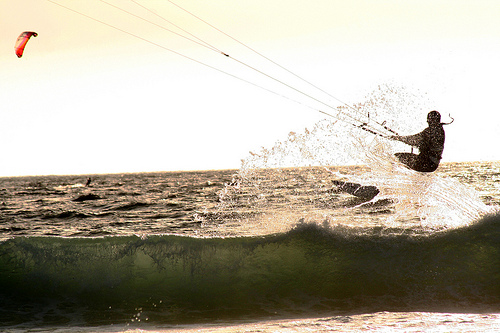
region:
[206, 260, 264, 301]
part of a water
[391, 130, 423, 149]
part of an elbow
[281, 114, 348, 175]
part of a splash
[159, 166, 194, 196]
part of a water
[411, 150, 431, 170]
part of a costume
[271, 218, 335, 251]
edge of a wave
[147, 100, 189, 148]
part of a cloud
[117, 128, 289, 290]
the water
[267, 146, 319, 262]
the water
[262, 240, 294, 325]
the water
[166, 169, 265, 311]
the water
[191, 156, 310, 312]
the water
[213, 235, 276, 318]
the water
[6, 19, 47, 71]
a red kite in the sky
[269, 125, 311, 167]
water spraying into the air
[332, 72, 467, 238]
a man surfing in the ocean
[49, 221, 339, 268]
a tall wave in the surf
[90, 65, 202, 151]
a white overcast sky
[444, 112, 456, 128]
a black cord blowing in the wind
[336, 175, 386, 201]
the front end of a surdboard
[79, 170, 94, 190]
a bird floating on the water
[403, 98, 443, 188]
a man wearing black swimwear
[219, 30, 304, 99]
strings connecting the man to the kite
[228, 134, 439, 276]
big splash of water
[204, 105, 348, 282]
big splash of water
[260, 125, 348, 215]
big splash of water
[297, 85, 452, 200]
a man is wind surfing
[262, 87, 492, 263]
the man is in the water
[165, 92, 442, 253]
the water is splashing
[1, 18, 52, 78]
a kite is flying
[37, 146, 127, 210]
a person in the water surfing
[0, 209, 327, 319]
the wave is rising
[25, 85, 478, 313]
the ocean is vast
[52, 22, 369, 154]
the sky is cloudy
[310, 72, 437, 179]
the man is holding the strings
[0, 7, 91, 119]
the kite is red